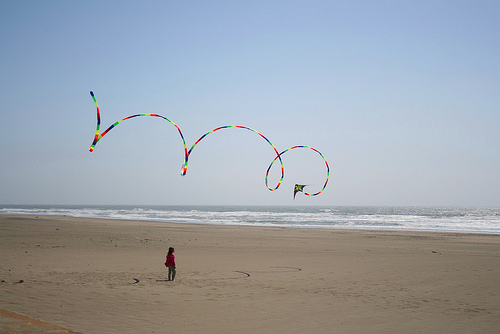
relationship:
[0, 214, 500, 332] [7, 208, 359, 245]
sand on beach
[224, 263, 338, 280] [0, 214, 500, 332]
reflection on sand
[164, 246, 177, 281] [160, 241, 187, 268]
person in shirt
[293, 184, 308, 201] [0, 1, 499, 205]
kite flying in sky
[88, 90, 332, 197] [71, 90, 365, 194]
long tail on kite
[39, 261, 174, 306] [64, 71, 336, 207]
shadow of kite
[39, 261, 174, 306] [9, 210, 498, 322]
shadow on ground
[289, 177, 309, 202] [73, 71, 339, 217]
kite with long tail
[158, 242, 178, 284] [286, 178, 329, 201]
person flying kite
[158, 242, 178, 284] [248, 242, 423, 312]
person on beach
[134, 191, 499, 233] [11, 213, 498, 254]
waves coming to shore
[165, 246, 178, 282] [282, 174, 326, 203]
woman watching kite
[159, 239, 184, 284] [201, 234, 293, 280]
woman on shore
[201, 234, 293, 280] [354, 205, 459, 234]
shore of ocean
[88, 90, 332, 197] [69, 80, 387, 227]
long tail of kite